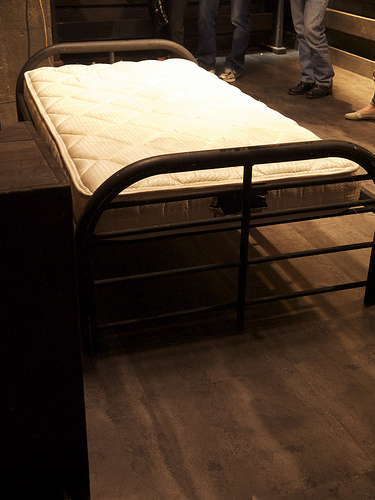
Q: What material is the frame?
A: Metal.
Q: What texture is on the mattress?
A: Quilting.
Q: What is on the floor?
A: Light brown tiles.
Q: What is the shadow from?
A: The frame of the bed.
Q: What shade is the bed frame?
A: Grey.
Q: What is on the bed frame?
A: Mattress.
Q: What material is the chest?
A: Wood.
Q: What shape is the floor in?
A: Dirty.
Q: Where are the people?
A: Next to the bed.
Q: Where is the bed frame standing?
A: On the floor.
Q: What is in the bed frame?
A: A mattress.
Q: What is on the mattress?
A: Nothing.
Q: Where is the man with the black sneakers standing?
A: Between the other two people.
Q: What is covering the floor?
A: A brown carpet.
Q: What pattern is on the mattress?
A: Diamonds.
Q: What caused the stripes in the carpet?
A: Vacuum cleaner.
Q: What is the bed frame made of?
A: Metal.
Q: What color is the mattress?
A: White.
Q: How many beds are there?
A: One.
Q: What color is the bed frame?
A: Brown.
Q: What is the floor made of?
A: Wood.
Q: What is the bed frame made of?
A: Metal.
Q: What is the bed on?
A: The floor.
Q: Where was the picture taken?
A: A bedroom.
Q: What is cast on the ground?
A: Shadows.